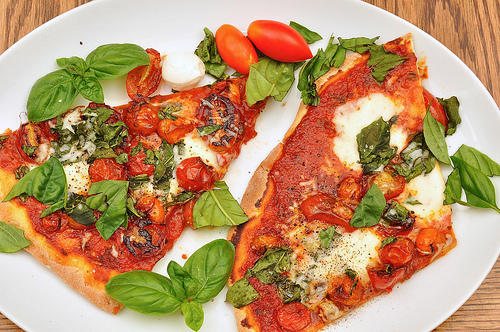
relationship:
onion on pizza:
[194, 92, 249, 146] [10, 24, 467, 315]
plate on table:
[2, 1, 499, 328] [31, 3, 498, 327]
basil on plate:
[23, 40, 152, 128] [21, 7, 468, 328]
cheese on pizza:
[399, 163, 446, 215] [229, 32, 456, 329]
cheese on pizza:
[399, 163, 446, 215] [2, 68, 273, 317]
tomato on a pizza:
[173, 156, 210, 198] [10, 24, 467, 315]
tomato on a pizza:
[119, 101, 160, 140] [10, 24, 467, 315]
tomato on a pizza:
[88, 153, 121, 185] [10, 24, 467, 315]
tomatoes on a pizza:
[126, 137, 154, 179] [10, 24, 467, 315]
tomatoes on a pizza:
[298, 190, 355, 227] [10, 24, 467, 315]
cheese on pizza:
[58, 145, 89, 184] [10, 24, 467, 315]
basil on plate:
[23, 40, 152, 128] [2, 1, 499, 328]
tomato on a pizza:
[173, 156, 210, 198] [2, 68, 273, 317]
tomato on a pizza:
[119, 101, 160, 140] [2, 68, 273, 317]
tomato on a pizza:
[87, 150, 126, 188] [2, 68, 273, 317]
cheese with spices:
[289, 93, 443, 293] [260, 169, 373, 300]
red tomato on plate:
[215, 21, 256, 81] [2, 1, 499, 328]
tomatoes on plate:
[244, 16, 318, 64] [2, 1, 499, 328]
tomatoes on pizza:
[91, 99, 188, 199] [10, 71, 268, 298]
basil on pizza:
[351, 186, 385, 226] [229, 32, 456, 329]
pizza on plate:
[2, 68, 273, 317] [2, 1, 499, 328]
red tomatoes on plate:
[213, 20, 315, 74] [2, 1, 499, 328]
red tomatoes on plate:
[213, 22, 257, 74] [63, 26, 476, 299]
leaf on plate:
[103, 268, 182, 318] [2, 1, 499, 328]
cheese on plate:
[155, 49, 210, 91] [21, 7, 468, 328]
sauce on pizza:
[9, 75, 259, 277] [0, 49, 292, 308]